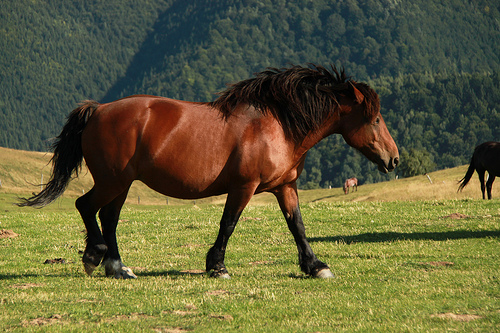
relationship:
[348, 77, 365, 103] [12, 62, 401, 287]
ear of horse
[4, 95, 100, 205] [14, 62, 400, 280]
tail of horse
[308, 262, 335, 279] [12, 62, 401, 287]
hoof of horse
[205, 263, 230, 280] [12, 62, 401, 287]
hoof of horse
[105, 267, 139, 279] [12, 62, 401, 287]
hoof of horse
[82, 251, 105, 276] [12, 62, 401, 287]
hoof of horse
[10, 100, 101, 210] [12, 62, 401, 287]
tail of horse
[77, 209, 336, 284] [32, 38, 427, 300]
legs of horse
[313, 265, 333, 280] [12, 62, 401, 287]
hoof of horse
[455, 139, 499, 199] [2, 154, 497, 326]
horse in field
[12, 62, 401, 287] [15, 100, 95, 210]
horse with hair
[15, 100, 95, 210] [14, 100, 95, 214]
hair on tail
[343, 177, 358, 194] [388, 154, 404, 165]
horse with nose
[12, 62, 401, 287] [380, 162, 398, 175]
horse with mouth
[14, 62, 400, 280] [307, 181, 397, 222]
horse on grass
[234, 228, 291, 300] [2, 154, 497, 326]
grass in field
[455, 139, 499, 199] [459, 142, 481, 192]
horse has tail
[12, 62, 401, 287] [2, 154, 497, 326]
horse in field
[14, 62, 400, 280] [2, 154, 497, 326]
horse in field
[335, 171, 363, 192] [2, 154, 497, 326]
horse in field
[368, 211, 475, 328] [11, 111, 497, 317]
grass in field